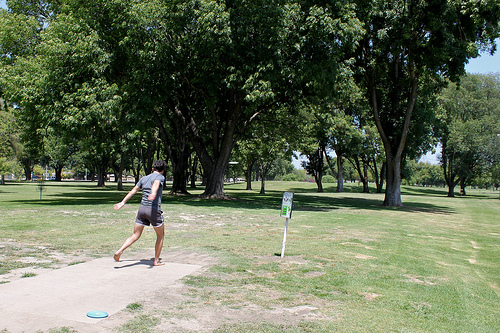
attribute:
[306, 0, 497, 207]
tree — large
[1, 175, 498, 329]
grass — short, green, brown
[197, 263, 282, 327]
grass — brown, short, green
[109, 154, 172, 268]
man — standing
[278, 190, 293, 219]
sign — green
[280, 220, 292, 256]
post — white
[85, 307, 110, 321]
disc — green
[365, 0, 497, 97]
leaves — green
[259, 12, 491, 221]
trees — blue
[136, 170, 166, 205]
t shirt — gray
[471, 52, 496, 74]
sky — blue